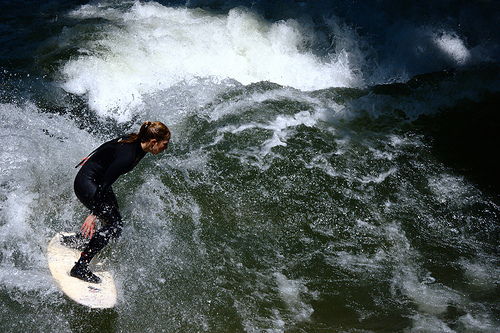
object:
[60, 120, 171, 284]
woman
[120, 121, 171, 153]
hair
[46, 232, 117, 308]
surfboard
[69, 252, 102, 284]
foot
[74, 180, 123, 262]
leg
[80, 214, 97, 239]
hand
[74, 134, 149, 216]
wetsuit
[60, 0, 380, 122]
surf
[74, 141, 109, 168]
zipper string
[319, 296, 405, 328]
water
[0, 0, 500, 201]
shadow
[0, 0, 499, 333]
water